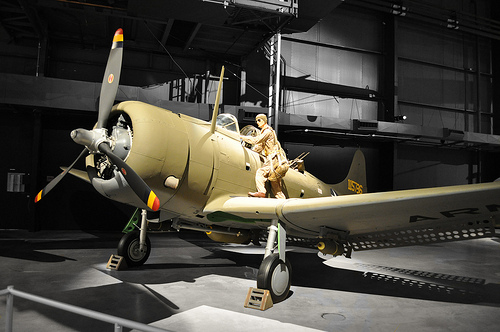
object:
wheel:
[116, 230, 154, 269]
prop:
[34, 26, 162, 213]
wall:
[0, 22, 499, 196]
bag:
[262, 147, 293, 182]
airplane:
[34, 27, 499, 303]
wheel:
[256, 253, 294, 303]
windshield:
[213, 113, 236, 127]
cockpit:
[213, 112, 262, 146]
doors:
[279, 0, 499, 198]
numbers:
[345, 178, 364, 194]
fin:
[337, 148, 366, 194]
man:
[241, 112, 292, 200]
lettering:
[407, 214, 439, 223]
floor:
[0, 227, 499, 331]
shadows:
[0, 233, 499, 331]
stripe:
[146, 190, 161, 211]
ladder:
[266, 34, 282, 138]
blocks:
[243, 286, 274, 311]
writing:
[108, 75, 116, 82]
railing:
[0, 29, 287, 112]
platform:
[0, 225, 499, 331]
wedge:
[243, 287, 273, 313]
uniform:
[241, 124, 291, 198]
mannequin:
[240, 112, 291, 199]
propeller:
[34, 27, 162, 213]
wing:
[204, 178, 499, 258]